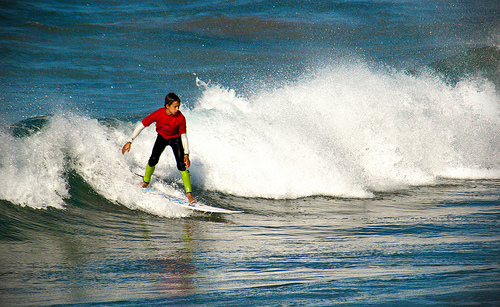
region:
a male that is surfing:
[121, 92, 240, 215]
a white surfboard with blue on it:
[128, 164, 243, 214]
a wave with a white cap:
[6, 58, 498, 218]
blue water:
[0, 1, 499, 303]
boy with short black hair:
[118, 93, 196, 200]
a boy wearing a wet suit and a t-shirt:
[121, 90, 197, 203]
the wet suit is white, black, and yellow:
[118, 120, 195, 192]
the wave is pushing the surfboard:
[4, 70, 490, 222]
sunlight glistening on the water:
[0, 205, 482, 305]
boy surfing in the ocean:
[42, 42, 263, 237]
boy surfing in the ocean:
[95, 84, 246, 226]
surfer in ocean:
[130, 91, 194, 202]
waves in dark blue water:
[250, 109, 347, 187]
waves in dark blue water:
[374, 22, 436, 122]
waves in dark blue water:
[92, 248, 173, 285]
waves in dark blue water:
[322, 192, 430, 272]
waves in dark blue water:
[255, 66, 323, 130]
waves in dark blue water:
[7, 105, 64, 155]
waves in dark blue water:
[285, 172, 380, 227]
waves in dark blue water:
[280, 83, 357, 138]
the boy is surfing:
[93, 53, 227, 257]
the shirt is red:
[130, 108, 210, 174]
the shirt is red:
[138, 100, 188, 155]